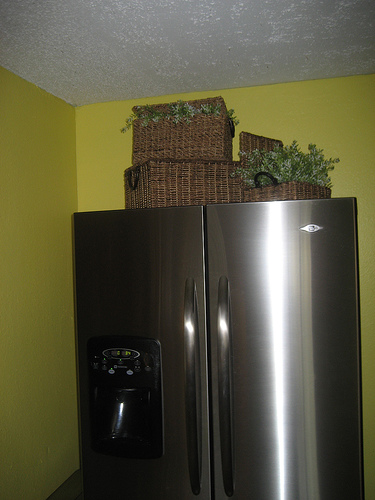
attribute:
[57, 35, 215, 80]
ceiling — white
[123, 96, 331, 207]
baskets — woven, brown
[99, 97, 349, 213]
baskets — wicker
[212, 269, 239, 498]
handle — stainless steel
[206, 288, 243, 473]
handle — stainless steel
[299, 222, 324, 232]
logo — metal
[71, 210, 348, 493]
refrigerator — two door refrigerator, stainless steel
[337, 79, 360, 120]
wall — yellow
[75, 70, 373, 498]
wall — yellow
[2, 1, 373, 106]
ceiling — popcorn ceiling, white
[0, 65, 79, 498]
wall — yellow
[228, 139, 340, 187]
plants — green, artificial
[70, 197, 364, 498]
fridge — stainless steel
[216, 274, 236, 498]
handle — long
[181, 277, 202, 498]
handle — long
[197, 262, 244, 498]
handle — brown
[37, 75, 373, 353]
wall — yellow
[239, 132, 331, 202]
basket — wicker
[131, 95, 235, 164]
basket — wicker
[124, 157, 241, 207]
basket — wicker, large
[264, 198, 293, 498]
glare — long